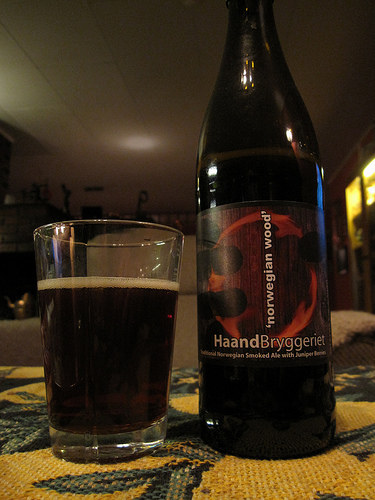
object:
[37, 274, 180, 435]
ale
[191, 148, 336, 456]
berries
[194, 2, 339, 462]
bottle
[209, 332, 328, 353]
haandbryggeriet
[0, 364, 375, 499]
floral design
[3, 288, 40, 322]
tea kettle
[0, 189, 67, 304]
fireplace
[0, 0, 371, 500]
background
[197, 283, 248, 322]
berry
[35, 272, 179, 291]
head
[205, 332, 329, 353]
writing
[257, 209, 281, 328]
writing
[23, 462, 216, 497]
coloring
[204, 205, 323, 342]
coloring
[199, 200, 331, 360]
bottle label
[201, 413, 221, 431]
glare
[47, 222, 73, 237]
glare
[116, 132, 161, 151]
light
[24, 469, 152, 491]
leaf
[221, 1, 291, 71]
neck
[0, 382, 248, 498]
pattern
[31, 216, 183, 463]
cup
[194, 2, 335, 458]
ale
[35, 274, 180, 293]
foam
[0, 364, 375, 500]
table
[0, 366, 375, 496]
cloth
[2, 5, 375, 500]
room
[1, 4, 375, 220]
ceiling